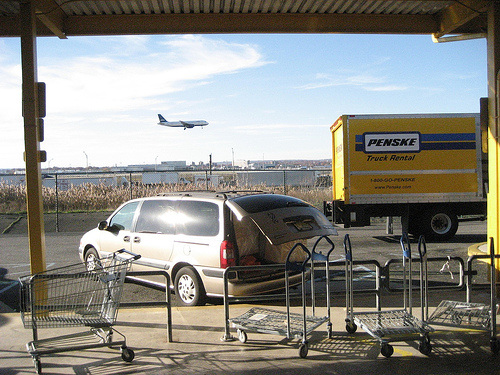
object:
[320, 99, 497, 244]
truck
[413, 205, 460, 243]
wheels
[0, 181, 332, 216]
grass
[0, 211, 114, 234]
field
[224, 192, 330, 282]
trunk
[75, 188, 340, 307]
car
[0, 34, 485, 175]
sky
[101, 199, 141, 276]
door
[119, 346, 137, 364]
wheel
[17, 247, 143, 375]
shopping cart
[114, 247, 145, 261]
handle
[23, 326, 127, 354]
rack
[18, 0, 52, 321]
post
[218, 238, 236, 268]
light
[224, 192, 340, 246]
door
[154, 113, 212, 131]
plane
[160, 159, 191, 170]
building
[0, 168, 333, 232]
fence